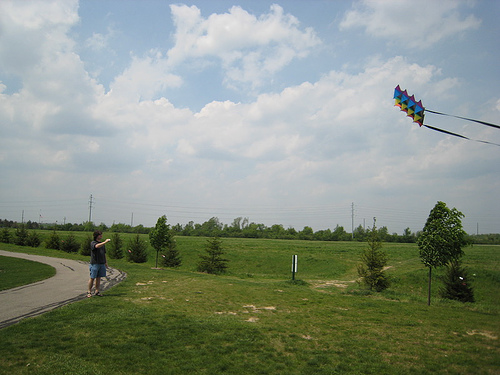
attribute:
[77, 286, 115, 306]
feet —  man's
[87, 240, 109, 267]
shirt — blue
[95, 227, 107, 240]
hair —  man's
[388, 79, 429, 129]
kite — flying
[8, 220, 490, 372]
grass — green, short, light green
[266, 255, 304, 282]
sign —  posted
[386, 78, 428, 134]
kite — tricolor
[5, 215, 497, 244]
line — of tree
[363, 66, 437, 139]
kite — colorful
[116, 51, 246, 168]
sky —  cloudy 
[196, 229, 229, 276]
tree — small, pine tree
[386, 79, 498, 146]
kite — multi-colored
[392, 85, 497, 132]
kite — Colorful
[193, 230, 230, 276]
tree — short, pine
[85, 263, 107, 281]
shorts —  light blue,  cargo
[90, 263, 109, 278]
shorts — light, blue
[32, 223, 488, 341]
green prairie — large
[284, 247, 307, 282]
sign —  White 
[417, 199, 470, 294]
tree — various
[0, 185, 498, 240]
power lines — for electrical power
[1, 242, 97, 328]
road — gray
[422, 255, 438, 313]
trunk — thin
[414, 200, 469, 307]
tree — tall, pine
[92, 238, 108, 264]
t-shirt — tee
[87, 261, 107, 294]
legs —  Person's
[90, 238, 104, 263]
t-shirt —   black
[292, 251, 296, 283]
post —   metal